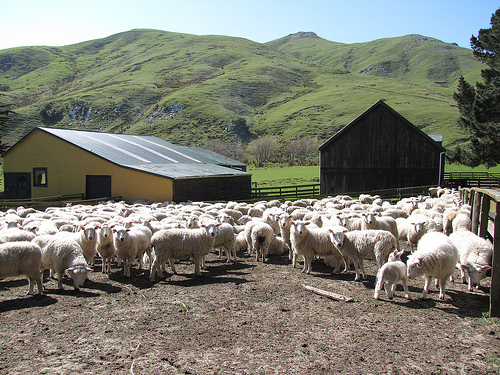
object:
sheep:
[0, 239, 46, 298]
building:
[3, 124, 253, 208]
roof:
[37, 126, 249, 177]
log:
[299, 278, 354, 300]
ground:
[0, 188, 499, 374]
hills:
[0, 28, 499, 160]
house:
[318, 100, 447, 199]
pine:
[445, 8, 499, 169]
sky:
[0, 0, 500, 54]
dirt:
[3, 254, 498, 372]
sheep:
[110, 226, 153, 278]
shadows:
[175, 271, 251, 289]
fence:
[244, 181, 329, 203]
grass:
[117, 27, 164, 47]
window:
[31, 163, 50, 189]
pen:
[1, 178, 499, 372]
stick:
[470, 187, 499, 206]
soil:
[0, 242, 499, 375]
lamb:
[376, 248, 409, 305]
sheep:
[401, 229, 460, 302]